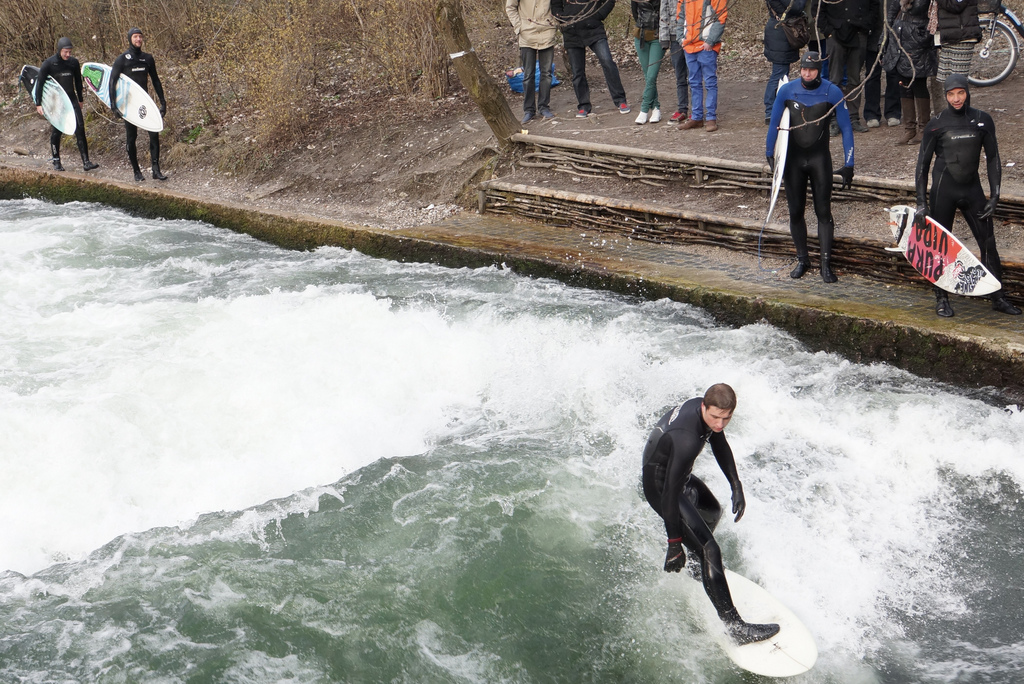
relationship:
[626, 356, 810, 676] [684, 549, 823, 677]
man on a surfboard